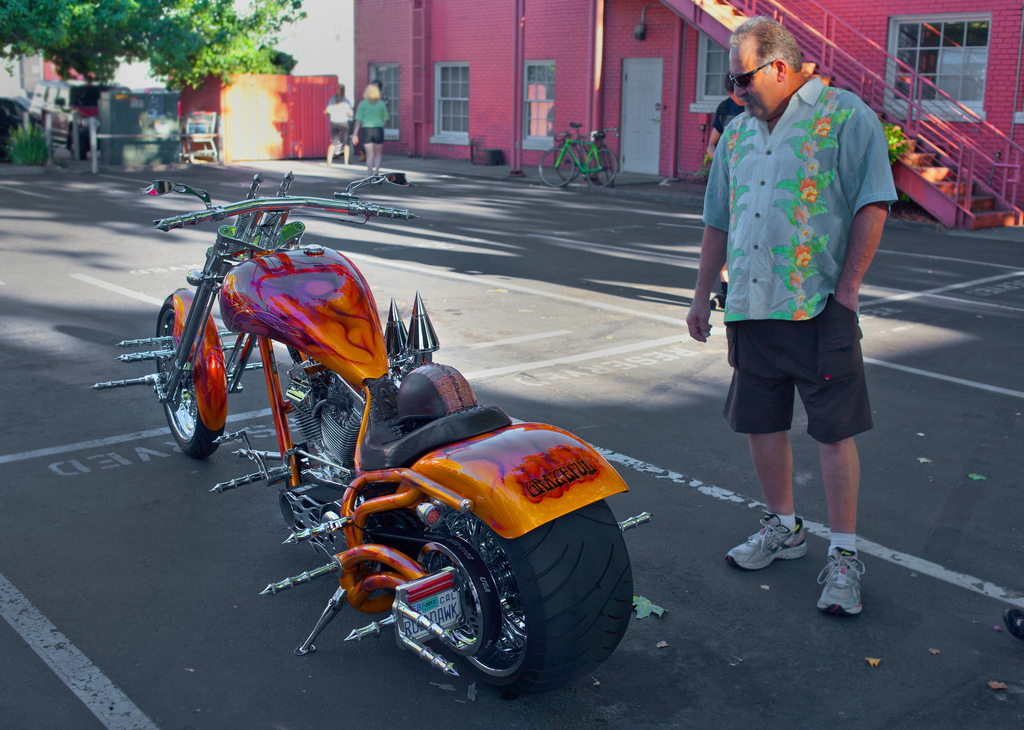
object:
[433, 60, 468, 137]
window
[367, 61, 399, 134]
window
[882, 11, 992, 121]
window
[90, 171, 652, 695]
motorcycle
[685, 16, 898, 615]
man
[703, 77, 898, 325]
shirt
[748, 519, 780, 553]
laces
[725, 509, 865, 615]
shoes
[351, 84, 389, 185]
person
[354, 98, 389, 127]
shirt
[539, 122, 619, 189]
bicycle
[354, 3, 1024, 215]
wall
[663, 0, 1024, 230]
staircase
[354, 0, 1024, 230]
building